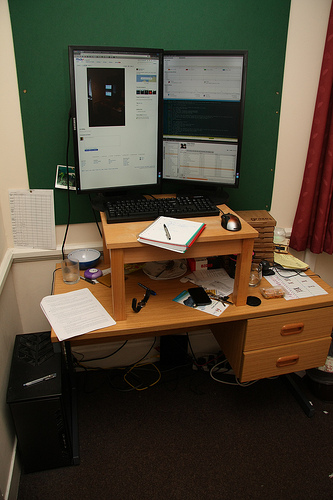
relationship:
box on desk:
[253, 226, 275, 231] [51, 193, 331, 411]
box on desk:
[242, 206, 279, 264] [51, 193, 331, 411]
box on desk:
[236, 209, 275, 266] [48, 263, 332, 342]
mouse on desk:
[221, 213, 241, 232] [51, 193, 331, 411]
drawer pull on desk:
[278, 321, 304, 336] [50, 203, 332, 464]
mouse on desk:
[218, 209, 242, 232] [50, 203, 332, 464]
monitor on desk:
[162, 49, 249, 204] [50, 203, 332, 464]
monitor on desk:
[71, 45, 161, 193] [50, 203, 332, 464]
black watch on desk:
[132, 289, 150, 312] [51, 193, 331, 411]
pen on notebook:
[163, 224, 172, 243] [145, 212, 197, 252]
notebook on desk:
[135, 214, 205, 255] [50, 203, 332, 464]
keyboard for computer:
[105, 193, 219, 224] [61, 37, 248, 229]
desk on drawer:
[51, 193, 331, 411] [248, 314, 332, 343]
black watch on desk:
[130, 283, 156, 311] [61, 219, 304, 392]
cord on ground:
[119, 359, 167, 391] [22, 360, 331, 498]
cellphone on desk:
[187, 285, 211, 305] [51, 193, 331, 411]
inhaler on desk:
[83, 265, 105, 280] [51, 193, 331, 411]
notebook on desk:
[137, 216, 207, 254] [97, 199, 254, 318]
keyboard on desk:
[103, 193, 219, 224] [50, 203, 332, 464]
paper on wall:
[5, 188, 58, 252] [3, 24, 289, 259]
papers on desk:
[26, 274, 196, 346] [81, 176, 276, 265]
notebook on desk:
[137, 216, 207, 254] [20, 206, 298, 387]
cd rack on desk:
[235, 203, 316, 287] [44, 209, 321, 376]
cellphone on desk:
[188, 286, 212, 305] [31, 239, 330, 369]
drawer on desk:
[235, 315, 329, 371] [51, 193, 331, 411]